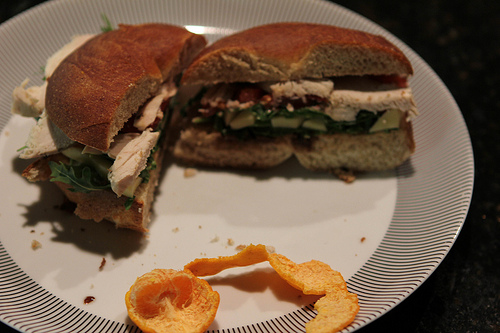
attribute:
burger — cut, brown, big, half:
[171, 19, 418, 173]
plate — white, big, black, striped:
[5, 0, 477, 330]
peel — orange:
[189, 234, 364, 332]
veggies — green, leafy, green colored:
[214, 105, 378, 141]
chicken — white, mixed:
[269, 78, 412, 112]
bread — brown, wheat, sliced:
[181, 20, 419, 85]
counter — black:
[0, 2, 500, 327]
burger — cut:
[24, 20, 204, 241]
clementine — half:
[120, 267, 220, 328]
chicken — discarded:
[16, 29, 96, 117]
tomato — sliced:
[235, 81, 273, 103]